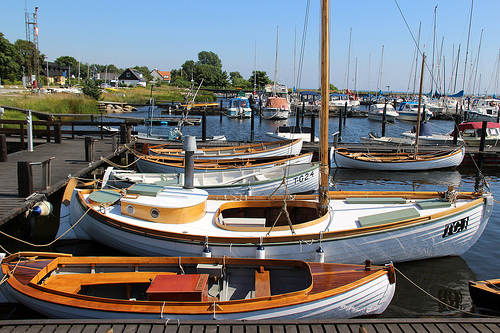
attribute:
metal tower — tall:
[25, 0, 38, 48]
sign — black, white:
[441, 216, 467, 237]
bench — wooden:
[253, 269, 270, 304]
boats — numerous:
[9, 69, 499, 324]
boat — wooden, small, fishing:
[7, 248, 398, 313]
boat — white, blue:
[328, 144, 469, 169]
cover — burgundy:
[455, 118, 498, 129]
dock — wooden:
[17, 276, 497, 331]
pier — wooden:
[3, 112, 138, 257]